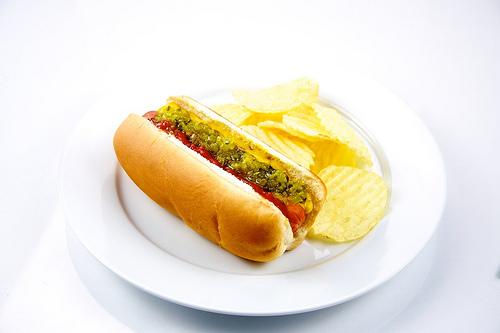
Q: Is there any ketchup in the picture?
A: Yes, there is ketchup.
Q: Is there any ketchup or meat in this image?
A: Yes, there is ketchup.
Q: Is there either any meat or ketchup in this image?
A: Yes, there is ketchup.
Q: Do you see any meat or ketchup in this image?
A: Yes, there is ketchup.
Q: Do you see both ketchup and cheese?
A: No, there is ketchup but no cheese.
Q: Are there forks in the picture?
A: No, there are no forks.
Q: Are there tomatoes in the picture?
A: No, there are no tomatoes.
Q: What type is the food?
A: The food is a bun.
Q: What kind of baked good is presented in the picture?
A: The baked good is a bun.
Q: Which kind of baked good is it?
A: The food is a bun.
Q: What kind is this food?
A: That is a bun.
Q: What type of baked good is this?
A: That is a bun.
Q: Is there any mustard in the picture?
A: Yes, there is mustard.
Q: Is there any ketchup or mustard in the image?
A: Yes, there is mustard.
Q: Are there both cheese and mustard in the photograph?
A: No, there is mustard but no cheese.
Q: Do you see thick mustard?
A: Yes, there is thick mustard.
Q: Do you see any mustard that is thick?
A: Yes, there is mustard that is thick.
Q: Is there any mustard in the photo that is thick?
A: Yes, there is mustard that is thick.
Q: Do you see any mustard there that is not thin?
A: Yes, there is thick mustard.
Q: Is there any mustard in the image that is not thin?
A: Yes, there is thick mustard.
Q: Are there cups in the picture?
A: No, there are no cups.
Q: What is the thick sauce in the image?
A: The sauce is mustard.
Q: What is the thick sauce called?
A: The sauce is mustard.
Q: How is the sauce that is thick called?
A: The sauce is mustard.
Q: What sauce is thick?
A: The sauce is mustard.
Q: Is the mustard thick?
A: Yes, the mustard is thick.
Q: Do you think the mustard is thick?
A: Yes, the mustard is thick.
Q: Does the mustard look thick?
A: Yes, the mustard is thick.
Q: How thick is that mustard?
A: The mustard is thick.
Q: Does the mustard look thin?
A: No, the mustard is thick.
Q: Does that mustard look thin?
A: No, the mustard is thick.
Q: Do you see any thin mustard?
A: No, there is mustard but it is thick.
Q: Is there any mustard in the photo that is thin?
A: No, there is mustard but it is thick.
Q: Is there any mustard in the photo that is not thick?
A: No, there is mustard but it is thick.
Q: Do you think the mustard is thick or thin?
A: The mustard is thick.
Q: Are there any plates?
A: Yes, there is a plate.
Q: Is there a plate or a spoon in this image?
A: Yes, there is a plate.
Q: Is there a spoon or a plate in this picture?
A: Yes, there is a plate.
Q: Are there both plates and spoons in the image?
A: No, there is a plate but no spoons.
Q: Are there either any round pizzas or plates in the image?
A: Yes, there is a round plate.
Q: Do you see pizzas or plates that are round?
A: Yes, the plate is round.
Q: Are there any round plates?
A: Yes, there is a round plate.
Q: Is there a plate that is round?
A: Yes, there is a plate that is round.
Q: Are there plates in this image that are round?
A: Yes, there is a plate that is round.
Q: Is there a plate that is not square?
A: Yes, there is a round plate.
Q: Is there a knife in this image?
A: No, there are no knives.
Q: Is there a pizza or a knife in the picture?
A: No, there are no knives or pizzas.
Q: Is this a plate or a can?
A: This is a plate.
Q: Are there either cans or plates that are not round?
A: No, there is a plate but it is round.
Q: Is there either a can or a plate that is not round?
A: No, there is a plate but it is round.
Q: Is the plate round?
A: Yes, the plate is round.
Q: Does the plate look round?
A: Yes, the plate is round.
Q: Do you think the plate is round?
A: Yes, the plate is round.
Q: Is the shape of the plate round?
A: Yes, the plate is round.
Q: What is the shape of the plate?
A: The plate is round.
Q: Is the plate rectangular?
A: No, the plate is round.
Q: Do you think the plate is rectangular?
A: No, the plate is round.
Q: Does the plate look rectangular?
A: No, the plate is round.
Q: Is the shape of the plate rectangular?
A: No, the plate is round.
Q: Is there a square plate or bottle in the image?
A: No, there is a plate but it is round.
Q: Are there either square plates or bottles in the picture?
A: No, there is a plate but it is round.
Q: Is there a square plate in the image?
A: No, there is a plate but it is round.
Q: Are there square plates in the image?
A: No, there is a plate but it is round.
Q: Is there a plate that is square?
A: No, there is a plate but it is round.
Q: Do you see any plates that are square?
A: No, there is a plate but it is round.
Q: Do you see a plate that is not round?
A: No, there is a plate but it is round.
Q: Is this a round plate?
A: Yes, this is a round plate.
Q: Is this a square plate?
A: No, this is a round plate.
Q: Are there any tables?
A: Yes, there is a table.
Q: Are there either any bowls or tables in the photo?
A: Yes, there is a table.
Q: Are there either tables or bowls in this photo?
A: Yes, there is a table.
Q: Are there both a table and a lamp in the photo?
A: No, there is a table but no lamps.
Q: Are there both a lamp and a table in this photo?
A: No, there is a table but no lamps.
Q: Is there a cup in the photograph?
A: No, there are no cups.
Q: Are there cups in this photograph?
A: No, there are no cups.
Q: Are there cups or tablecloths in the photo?
A: No, there are no cups or tablecloths.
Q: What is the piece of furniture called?
A: The piece of furniture is a table.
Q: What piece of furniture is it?
A: The piece of furniture is a table.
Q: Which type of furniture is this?
A: That is a table.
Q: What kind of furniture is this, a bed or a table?
A: That is a table.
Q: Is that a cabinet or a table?
A: That is a table.